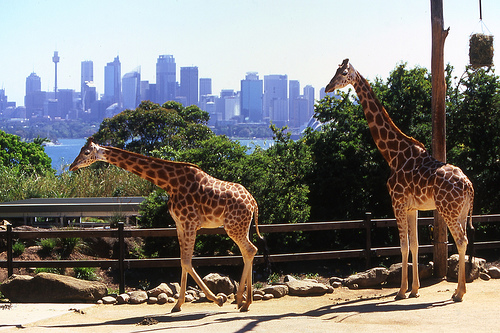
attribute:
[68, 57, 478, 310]
giraffes — brown, tall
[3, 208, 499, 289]
fence — brown, wooden, low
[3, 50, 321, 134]
buildings — tall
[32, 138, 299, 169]
water — blue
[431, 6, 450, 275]
pole — brown, wooden, wood, tall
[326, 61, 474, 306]
giraffe — tall, walking, brown, tan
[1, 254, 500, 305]
rocks — brown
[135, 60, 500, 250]
bushes — green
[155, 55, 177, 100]
building — tallest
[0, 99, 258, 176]
trees — green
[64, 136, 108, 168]
head — lowered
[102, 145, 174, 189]
neck — lowered, tall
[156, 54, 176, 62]
roof — black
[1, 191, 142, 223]
tracks — grey